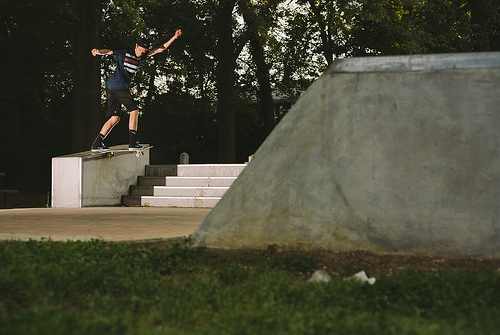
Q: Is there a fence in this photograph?
A: No, there are no fences.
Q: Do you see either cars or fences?
A: No, there are no fences or cars.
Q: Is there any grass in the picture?
A: Yes, there is grass.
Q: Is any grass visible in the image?
A: Yes, there is grass.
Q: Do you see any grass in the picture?
A: Yes, there is grass.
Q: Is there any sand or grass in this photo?
A: Yes, there is grass.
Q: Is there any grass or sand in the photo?
A: Yes, there is grass.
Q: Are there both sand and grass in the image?
A: No, there is grass but no sand.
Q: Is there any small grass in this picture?
A: Yes, there is small grass.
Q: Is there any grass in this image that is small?
A: Yes, there is grass that is small.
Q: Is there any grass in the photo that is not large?
A: Yes, there is small grass.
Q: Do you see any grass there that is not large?
A: Yes, there is small grass.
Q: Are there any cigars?
A: No, there are no cigars.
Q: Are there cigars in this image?
A: No, there are no cigars.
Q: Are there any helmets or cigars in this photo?
A: No, there are no cigars or helmets.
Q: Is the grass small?
A: Yes, the grass is small.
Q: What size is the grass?
A: The grass is small.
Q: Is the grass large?
A: No, the grass is small.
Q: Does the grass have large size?
A: No, the grass is small.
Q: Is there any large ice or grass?
A: No, there is grass but it is small.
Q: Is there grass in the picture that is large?
A: No, there is grass but it is small.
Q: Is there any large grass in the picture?
A: No, there is grass but it is small.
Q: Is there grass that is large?
A: No, there is grass but it is small.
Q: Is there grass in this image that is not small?
A: No, there is grass but it is small.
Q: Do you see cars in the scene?
A: No, there are no cars.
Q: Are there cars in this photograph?
A: No, there are no cars.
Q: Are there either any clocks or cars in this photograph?
A: No, there are no cars or clocks.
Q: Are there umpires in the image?
A: No, there are no umpires.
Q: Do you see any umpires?
A: No, there are no umpires.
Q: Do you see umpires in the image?
A: No, there are no umpires.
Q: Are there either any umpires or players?
A: No, there are no umpires or players.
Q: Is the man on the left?
A: Yes, the man is on the left of the image.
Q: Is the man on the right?
A: No, the man is on the left of the image.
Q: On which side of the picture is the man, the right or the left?
A: The man is on the left of the image.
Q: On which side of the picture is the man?
A: The man is on the left of the image.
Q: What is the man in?
A: The man is in the air.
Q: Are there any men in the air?
A: Yes, there is a man in the air.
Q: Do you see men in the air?
A: Yes, there is a man in the air.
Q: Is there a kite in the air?
A: No, there is a man in the air.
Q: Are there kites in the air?
A: No, there is a man in the air.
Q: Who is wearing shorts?
A: The man is wearing shorts.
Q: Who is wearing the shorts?
A: The man is wearing shorts.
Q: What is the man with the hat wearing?
A: The man is wearing shorts.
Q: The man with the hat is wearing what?
A: The man is wearing shorts.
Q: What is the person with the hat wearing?
A: The man is wearing shorts.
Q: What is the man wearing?
A: The man is wearing shorts.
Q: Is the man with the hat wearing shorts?
A: Yes, the man is wearing shorts.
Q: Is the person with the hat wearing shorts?
A: Yes, the man is wearing shorts.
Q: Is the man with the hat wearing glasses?
A: No, the man is wearing shorts.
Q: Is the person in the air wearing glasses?
A: No, the man is wearing shorts.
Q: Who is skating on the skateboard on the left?
A: The man is skating on the skateboard.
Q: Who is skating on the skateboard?
A: The man is skating on the skateboard.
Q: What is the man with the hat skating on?
A: The man is skating on the skateboard.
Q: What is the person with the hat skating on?
A: The man is skating on the skateboard.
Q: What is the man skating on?
A: The man is skating on the skateboard.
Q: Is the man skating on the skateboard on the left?
A: Yes, the man is skating on the skateboard.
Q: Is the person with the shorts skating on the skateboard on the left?
A: Yes, the man is skating on the skateboard.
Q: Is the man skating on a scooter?
A: No, the man is skating on the skateboard.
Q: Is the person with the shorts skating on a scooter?
A: No, the man is skating on the skateboard.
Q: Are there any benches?
A: No, there are no benches.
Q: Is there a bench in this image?
A: No, there are no benches.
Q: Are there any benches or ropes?
A: No, there are no benches or ropes.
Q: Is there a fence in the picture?
A: No, there are no fences.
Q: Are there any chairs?
A: No, there are no chairs.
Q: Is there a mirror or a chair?
A: No, there are no chairs or mirrors.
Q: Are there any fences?
A: No, there are no fences.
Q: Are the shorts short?
A: Yes, the shorts are short.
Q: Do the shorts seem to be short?
A: Yes, the shorts are short.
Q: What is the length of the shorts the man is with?
A: The shorts are short.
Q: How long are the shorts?
A: The shorts are short.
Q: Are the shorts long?
A: No, the shorts are short.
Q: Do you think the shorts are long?
A: No, the shorts are short.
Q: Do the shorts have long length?
A: No, the shorts are short.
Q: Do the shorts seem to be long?
A: No, the shorts are short.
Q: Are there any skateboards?
A: Yes, there is a skateboard.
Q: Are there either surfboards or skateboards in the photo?
A: Yes, there is a skateboard.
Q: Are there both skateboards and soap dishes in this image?
A: No, there is a skateboard but no soap dishes.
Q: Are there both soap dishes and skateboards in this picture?
A: No, there is a skateboard but no soap dishes.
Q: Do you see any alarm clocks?
A: No, there are no alarm clocks.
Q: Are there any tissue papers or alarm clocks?
A: No, there are no alarm clocks or tissue papers.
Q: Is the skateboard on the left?
A: Yes, the skateboard is on the left of the image.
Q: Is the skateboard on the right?
A: No, the skateboard is on the left of the image.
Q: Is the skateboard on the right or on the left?
A: The skateboard is on the left of the image.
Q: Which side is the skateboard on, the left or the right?
A: The skateboard is on the left of the image.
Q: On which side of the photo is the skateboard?
A: The skateboard is on the left of the image.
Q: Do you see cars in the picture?
A: No, there are no cars.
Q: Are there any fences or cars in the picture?
A: No, there are no cars or fences.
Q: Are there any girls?
A: No, there are no girls.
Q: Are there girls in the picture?
A: No, there are no girls.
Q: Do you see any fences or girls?
A: No, there are no girls or fences.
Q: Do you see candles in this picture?
A: No, there are no candles.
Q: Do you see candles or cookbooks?
A: No, there are no candles or cookbooks.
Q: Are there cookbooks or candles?
A: No, there are no candles or cookbooks.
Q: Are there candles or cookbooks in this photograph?
A: No, there are no candles or cookbooks.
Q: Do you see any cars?
A: No, there are no cars.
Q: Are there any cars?
A: No, there are no cars.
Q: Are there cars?
A: No, there are no cars.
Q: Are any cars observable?
A: No, there are no cars.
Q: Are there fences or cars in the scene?
A: No, there are no cars or fences.